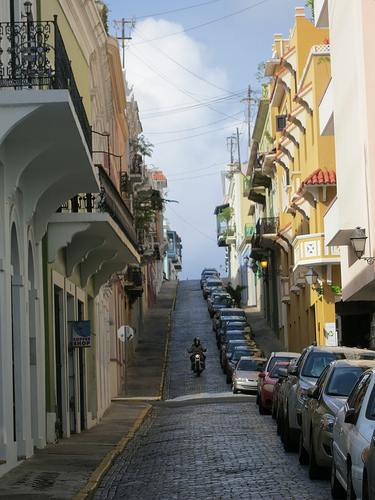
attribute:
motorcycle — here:
[186, 336, 209, 375]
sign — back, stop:
[108, 312, 163, 359]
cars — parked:
[246, 331, 340, 444]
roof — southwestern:
[269, 46, 356, 175]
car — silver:
[335, 382, 364, 422]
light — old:
[237, 231, 303, 281]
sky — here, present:
[119, 50, 257, 179]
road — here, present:
[137, 265, 232, 345]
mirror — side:
[325, 381, 372, 435]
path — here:
[139, 294, 184, 367]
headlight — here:
[314, 404, 365, 452]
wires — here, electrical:
[126, 26, 192, 120]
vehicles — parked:
[203, 275, 366, 453]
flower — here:
[111, 176, 174, 226]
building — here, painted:
[28, 31, 182, 309]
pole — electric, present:
[102, 21, 149, 65]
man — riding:
[179, 330, 215, 347]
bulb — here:
[250, 242, 276, 276]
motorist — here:
[175, 333, 233, 363]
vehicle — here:
[215, 301, 254, 330]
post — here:
[239, 111, 267, 136]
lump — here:
[170, 366, 231, 403]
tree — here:
[277, 275, 327, 329]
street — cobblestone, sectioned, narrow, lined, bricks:
[128, 279, 259, 496]